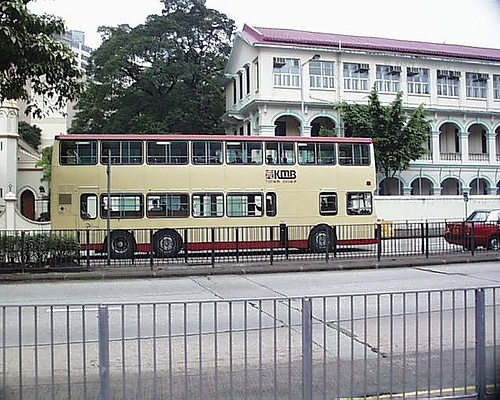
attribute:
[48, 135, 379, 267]
bus — red, tan, double decker, beige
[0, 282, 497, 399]
railing — metal, in foreground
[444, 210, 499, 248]
car — red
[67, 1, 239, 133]
tree — large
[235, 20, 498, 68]
roof — red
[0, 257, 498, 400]
pavement — cracked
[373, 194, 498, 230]
wall — white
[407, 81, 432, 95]
rails — white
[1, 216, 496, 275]
fence — dividing road, long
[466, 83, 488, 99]
balcony — white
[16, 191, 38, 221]
door — red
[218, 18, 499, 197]
building — white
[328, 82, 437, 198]
tree — green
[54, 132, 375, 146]
roof — red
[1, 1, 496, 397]
photo — street scene